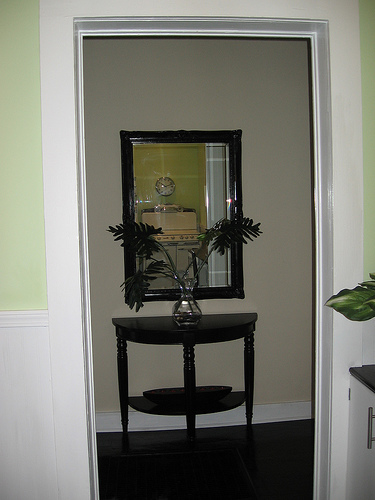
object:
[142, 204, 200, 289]
refrigerator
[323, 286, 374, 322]
leaf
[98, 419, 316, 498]
floor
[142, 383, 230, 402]
bowl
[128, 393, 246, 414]
shelf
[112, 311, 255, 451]
stand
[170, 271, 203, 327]
vase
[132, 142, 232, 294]
mirror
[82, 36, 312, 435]
wall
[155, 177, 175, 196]
clock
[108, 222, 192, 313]
plant clipping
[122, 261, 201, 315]
plant clipping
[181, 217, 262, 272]
plant clipping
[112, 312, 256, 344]
shelf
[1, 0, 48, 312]
wall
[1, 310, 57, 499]
border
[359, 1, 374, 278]
wall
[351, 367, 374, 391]
border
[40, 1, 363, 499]
door frame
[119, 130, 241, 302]
frame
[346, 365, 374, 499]
cabinet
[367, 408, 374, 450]
handle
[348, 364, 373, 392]
countertop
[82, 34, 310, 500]
doorway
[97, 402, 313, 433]
baseboard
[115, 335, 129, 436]
leg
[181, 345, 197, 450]
leg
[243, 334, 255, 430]
leg